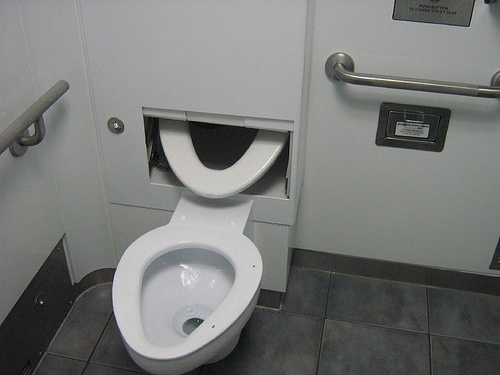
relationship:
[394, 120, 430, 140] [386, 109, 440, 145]
label on door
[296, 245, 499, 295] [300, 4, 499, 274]
molding beneath wall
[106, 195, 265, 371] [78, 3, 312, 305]
toilet attached to wall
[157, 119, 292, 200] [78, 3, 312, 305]
toilet seat in wall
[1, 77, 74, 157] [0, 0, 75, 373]
bar attached to wall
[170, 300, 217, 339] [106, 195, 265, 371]
water in toilet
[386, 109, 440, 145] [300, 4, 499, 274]
door in wall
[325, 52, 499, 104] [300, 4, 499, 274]
bar on wall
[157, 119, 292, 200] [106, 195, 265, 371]
toilet seat for toilet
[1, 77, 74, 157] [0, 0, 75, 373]
bar on wall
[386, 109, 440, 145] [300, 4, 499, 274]
door on wall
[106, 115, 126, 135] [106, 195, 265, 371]
flush button for toilet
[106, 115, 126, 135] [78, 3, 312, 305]
flush button on wall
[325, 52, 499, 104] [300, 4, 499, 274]
bar affixed to wall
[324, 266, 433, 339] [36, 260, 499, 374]
tile on floor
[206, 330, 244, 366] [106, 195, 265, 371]
base of toilet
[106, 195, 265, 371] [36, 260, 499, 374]
toilet on floor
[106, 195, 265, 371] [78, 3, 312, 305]
toilet on wall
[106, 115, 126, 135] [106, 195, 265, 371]
flush button to toilet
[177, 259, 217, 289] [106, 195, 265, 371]
light reflected in toilet